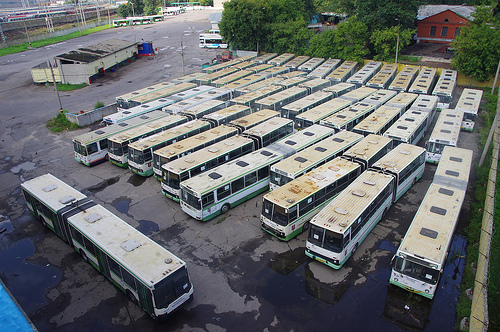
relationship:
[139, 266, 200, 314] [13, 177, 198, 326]
windshield on bus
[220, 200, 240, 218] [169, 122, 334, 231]
wheel on bus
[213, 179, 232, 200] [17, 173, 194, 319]
windows on bus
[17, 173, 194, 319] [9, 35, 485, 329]
bus in parking lot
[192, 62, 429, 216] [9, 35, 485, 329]
buses in parking lot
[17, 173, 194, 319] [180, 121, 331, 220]
bus in front of bus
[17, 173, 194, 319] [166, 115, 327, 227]
bus in front of bus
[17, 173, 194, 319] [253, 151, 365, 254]
bus in front of bus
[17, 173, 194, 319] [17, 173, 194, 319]
bus in front of bus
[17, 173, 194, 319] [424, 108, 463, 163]
bus in front of bus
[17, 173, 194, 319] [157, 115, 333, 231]
bus in front of bus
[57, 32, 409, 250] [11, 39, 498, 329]
buses in lot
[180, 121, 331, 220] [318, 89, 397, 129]
bus in front of bus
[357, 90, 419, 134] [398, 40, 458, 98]
bus in front of bus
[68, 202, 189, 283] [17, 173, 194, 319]
top of bus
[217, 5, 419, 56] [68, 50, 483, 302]
trees behind busses